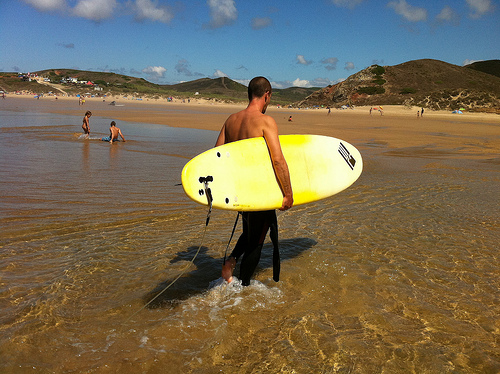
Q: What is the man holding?
A: Surfboard.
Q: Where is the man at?
A: Beach.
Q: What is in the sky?
A: Clouds.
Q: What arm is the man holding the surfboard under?
A: Right.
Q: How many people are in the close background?
A: Two.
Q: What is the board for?
A: Surfing.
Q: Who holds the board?
A: A man.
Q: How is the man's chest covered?
A: It is not.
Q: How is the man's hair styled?
A: Crewcut.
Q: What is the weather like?
A: Sunny.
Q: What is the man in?
A: Water.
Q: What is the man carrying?
A: Surfboard.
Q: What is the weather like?
A: Warm.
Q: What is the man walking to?
A: Beach.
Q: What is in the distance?
A: Mountains.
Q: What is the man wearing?
A: Wetsuit.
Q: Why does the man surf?
A: Sport.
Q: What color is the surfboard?
A: Yellow.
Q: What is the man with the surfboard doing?
A: Walking.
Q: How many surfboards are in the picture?
A: One.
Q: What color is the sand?
A: Brown.